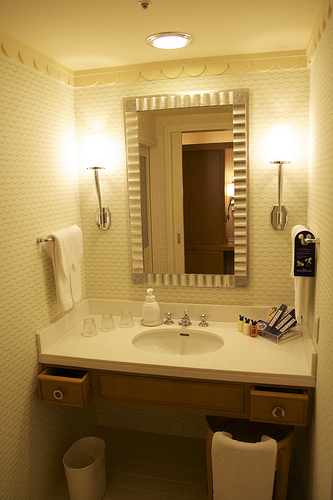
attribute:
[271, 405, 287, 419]
handle — metal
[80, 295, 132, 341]
cups —  plastic,  upside down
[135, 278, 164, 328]
dispenser —  large,  of soap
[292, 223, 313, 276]
hanger —  micky mouse,  for door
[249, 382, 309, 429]
drawer —  small,  brown,   wooden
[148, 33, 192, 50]
ceiling light —  bright white, at ceiling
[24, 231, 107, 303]
towel —  white, for bath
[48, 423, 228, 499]
floor — tiled